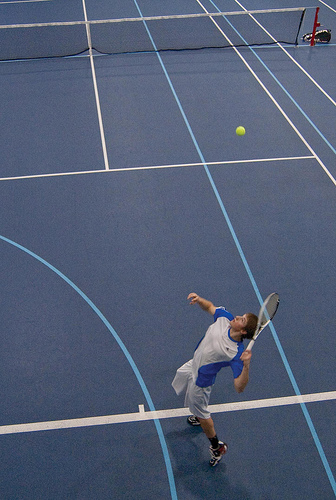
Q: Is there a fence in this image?
A: No, there are no fences.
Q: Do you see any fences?
A: No, there are no fences.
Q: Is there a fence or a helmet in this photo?
A: No, there are no fences or helmets.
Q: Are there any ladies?
A: No, there are no ladies.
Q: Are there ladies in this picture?
A: No, there are no ladies.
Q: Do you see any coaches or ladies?
A: No, there are no ladies or coaches.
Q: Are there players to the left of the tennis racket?
A: Yes, there is a player to the left of the tennis racket.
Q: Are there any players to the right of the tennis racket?
A: No, the player is to the left of the tennis racket.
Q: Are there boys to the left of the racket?
A: No, there is a player to the left of the racket.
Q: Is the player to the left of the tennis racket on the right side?
A: Yes, the player is to the left of the tennis racket.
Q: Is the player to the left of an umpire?
A: No, the player is to the left of the tennis racket.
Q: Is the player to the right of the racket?
A: No, the player is to the left of the racket.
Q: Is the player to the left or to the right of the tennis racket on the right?
A: The player is to the left of the tennis racket.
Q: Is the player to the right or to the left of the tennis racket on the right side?
A: The player is to the left of the tennis racket.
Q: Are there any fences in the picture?
A: No, there are no fences.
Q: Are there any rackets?
A: Yes, there is a racket.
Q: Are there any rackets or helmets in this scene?
A: Yes, there is a racket.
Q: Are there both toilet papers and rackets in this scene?
A: No, there is a racket but no toilet papers.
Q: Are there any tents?
A: No, there are no tents.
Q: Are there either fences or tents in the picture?
A: No, there are no tents or fences.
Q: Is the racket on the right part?
A: Yes, the racket is on the right of the image.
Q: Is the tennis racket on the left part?
A: No, the tennis racket is on the right of the image.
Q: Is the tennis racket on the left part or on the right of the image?
A: The tennis racket is on the right of the image.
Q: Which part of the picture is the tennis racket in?
A: The tennis racket is on the right of the image.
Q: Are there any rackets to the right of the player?
A: Yes, there is a racket to the right of the player.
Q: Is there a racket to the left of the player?
A: No, the racket is to the right of the player.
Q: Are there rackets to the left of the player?
A: No, the racket is to the right of the player.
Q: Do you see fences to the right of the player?
A: No, there is a racket to the right of the player.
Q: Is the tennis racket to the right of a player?
A: Yes, the tennis racket is to the right of a player.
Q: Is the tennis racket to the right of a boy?
A: No, the tennis racket is to the right of a player.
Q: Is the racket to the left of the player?
A: No, the racket is to the right of the player.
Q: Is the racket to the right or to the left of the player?
A: The racket is to the right of the player.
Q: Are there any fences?
A: No, there are no fences.